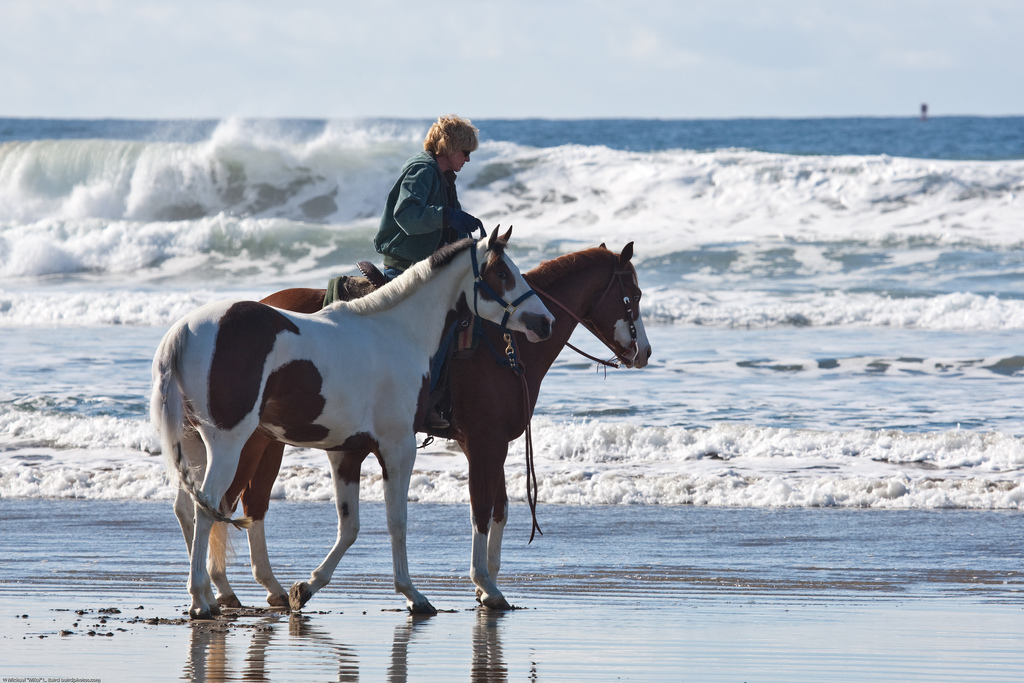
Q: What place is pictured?
A: It is an ocean.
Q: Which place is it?
A: It is an ocean.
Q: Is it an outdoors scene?
A: Yes, it is outdoors.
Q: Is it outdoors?
A: Yes, it is outdoors.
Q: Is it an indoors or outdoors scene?
A: It is outdoors.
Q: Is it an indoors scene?
A: No, it is outdoors.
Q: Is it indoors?
A: No, it is outdoors.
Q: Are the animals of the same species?
A: Yes, all the animals are horses.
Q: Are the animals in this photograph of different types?
A: No, all the animals are horses.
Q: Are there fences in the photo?
A: No, there are no fences.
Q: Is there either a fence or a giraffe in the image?
A: No, there are no fences or giraffes.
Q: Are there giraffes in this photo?
A: No, there are no giraffes.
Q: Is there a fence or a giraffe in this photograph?
A: No, there are no giraffes or fences.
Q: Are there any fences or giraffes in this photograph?
A: No, there are no giraffes or fences.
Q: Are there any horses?
A: Yes, there is a horse.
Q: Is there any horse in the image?
A: Yes, there is a horse.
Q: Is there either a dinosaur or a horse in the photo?
A: Yes, there is a horse.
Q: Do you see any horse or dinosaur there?
A: Yes, there is a horse.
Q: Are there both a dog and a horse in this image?
A: No, there is a horse but no dogs.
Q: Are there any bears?
A: No, there are no bears.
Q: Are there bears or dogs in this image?
A: No, there are no bears or dogs.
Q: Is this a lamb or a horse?
A: This is a horse.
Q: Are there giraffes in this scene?
A: No, there are no giraffes.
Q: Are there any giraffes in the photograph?
A: No, there are no giraffes.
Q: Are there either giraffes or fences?
A: No, there are no giraffes or fences.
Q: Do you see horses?
A: Yes, there is a horse.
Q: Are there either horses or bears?
A: Yes, there is a horse.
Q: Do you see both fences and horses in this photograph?
A: No, there is a horse but no fences.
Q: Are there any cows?
A: No, there are no cows.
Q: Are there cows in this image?
A: No, there are no cows.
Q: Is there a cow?
A: No, there are no cows.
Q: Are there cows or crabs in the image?
A: No, there are no cows or crabs.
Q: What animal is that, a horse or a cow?
A: That is a horse.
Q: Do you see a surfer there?
A: No, there are no surfers.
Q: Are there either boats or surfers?
A: No, there are no surfers or boats.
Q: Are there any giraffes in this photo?
A: No, there are no giraffes.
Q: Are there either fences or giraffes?
A: No, there are no giraffes or fences.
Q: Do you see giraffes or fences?
A: No, there are no giraffes or fences.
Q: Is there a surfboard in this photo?
A: No, there are no surfboards.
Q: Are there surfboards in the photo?
A: No, there are no surfboards.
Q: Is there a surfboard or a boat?
A: No, there are no surfboards or boats.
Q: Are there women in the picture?
A: Yes, there is a woman.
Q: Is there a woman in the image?
A: Yes, there is a woman.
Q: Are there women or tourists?
A: Yes, there is a woman.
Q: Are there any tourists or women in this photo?
A: Yes, there is a woman.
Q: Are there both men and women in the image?
A: No, there is a woman but no men.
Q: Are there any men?
A: No, there are no men.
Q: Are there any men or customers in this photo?
A: No, there are no men or customers.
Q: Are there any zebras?
A: No, there are no zebras.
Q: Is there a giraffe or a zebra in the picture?
A: No, there are no zebras or giraffes.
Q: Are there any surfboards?
A: No, there are no surfboards.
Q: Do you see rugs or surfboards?
A: No, there are no surfboards or rugs.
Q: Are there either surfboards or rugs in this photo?
A: No, there are no surfboards or rugs.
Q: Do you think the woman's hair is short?
A: Yes, the hair is short.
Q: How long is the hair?
A: The hair is short.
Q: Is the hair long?
A: No, the hair is short.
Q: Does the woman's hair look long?
A: No, the hair is short.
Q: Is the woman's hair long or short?
A: The hair is short.